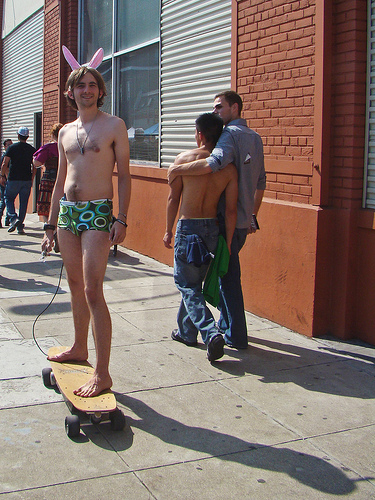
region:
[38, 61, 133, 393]
Man with bunny ears wearing swimsuit riding skateboard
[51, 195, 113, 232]
Green swimsuit on man with bunny ears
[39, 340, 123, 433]
Brown skateboard under man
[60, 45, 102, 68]
Pink bunny ears on man riding skateboard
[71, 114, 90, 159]
Necklace on man wearing bunny ears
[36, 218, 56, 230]
Dark wristband worn by man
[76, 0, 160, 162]
Window behind skateboarder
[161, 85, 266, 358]
Couple walking down the sidewalk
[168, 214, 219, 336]
Blue pants of man walking on sidewalk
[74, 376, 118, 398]
Bare foot of man on skateboard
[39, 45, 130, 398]
man riding skateboard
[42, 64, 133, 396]
man is barefoot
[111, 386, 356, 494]
man casts shadow on sidewalk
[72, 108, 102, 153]
man wearing necklace around neck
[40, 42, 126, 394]
man is shirtless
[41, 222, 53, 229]
man wearing black watch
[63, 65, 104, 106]
man has long brown hair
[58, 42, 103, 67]
pink bunny ears on top of man's head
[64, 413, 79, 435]
wheel on skateboard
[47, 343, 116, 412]
brown wooden skateboard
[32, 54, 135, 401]
a person in the street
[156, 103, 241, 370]
a person in the street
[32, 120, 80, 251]
a person in the street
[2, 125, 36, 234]
a person in the street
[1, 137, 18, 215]
a person in the street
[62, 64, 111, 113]
the head of a person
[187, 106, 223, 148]
the head of a person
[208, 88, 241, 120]
the head of a person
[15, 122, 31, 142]
the head of a person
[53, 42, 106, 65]
Pink rabbit ears on man's head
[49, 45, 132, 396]
Man wearing pink rabbit ears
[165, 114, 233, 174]
Left arm of man in blue shirt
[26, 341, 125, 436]
Skateboard with man on it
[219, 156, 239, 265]
Right arm of man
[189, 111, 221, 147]
Head of man with blue jeans no shirt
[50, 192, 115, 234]
Swim trunks of man on skate board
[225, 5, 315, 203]
Orange brick side of building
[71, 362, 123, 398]
Left foot of skateboarder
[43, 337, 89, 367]
Right foot of skateboarder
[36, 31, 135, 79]
man wearing bunny ears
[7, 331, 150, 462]
man writing a motorcycle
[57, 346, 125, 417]
bare feet of the man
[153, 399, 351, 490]
shadow casted by the man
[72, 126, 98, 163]
the neckalce of the man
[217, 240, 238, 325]
a green shirt hanging from side of man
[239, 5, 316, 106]
side of brick building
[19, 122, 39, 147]
man in the hat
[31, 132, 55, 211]
lady walking in the street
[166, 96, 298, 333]
two guys walking with each other